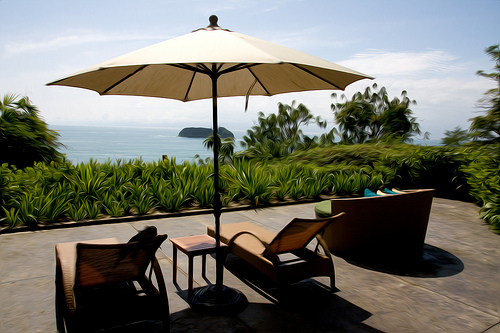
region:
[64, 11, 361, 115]
tan umbrella on porch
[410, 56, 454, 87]
white clouds in blue sky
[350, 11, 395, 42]
white clouds in blue sky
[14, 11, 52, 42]
white clouds in blue sky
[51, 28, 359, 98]
tan colored open umbrella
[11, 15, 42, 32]
white clouds in blue sky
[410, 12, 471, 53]
white clouds in blue sky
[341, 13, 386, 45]
white clouds in blue sky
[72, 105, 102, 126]
white clouds in blue sky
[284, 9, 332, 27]
white clouds in blue sky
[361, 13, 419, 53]
white clouds in blue sky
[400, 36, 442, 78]
white clouds in blue sky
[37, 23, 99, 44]
white clouds in blue sky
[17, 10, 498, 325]
a seating area on a patio.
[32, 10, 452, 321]
Lawn furniture on a large deck.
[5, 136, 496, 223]
Low green bushes surround the patio.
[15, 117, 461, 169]
A body of water.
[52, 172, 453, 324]
A seating area looking out over the water.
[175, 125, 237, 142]
A large rock in the water.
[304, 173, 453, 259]
A round wicker seat with pillows.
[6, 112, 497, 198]
A view of the ocean.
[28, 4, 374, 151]
this is an umbrella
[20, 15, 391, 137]
the umbrella is tan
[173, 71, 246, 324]
pole for the umbrella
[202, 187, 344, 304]
a patio recliner chair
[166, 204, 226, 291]
a square wooden table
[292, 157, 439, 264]
a round patio chair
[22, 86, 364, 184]
the ocean in the distance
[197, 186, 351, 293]
patio chair is brown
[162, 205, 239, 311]
table is brown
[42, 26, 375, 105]
The opened top of a tan umbrella.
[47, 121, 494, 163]
Blue ocean going across.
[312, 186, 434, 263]
A larger brown and green high back chair with blue and white pillows.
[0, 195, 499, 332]
A large tiled area around the patio.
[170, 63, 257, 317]
Black poles holding up the umbrella and keeping it open.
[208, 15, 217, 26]
Round black top on an umbrella.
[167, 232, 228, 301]
Small wood table between the chairs.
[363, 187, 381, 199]
Most visible blue pillow in a chair.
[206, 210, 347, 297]
More visible beige chair.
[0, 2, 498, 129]
Blue sky with white clouds.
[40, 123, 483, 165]
blue and clear ocean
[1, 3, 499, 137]
blue sky with clouds in it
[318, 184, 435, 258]
green and brown chair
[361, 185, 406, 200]
blue and yellow pillows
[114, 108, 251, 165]
A rock in the middle of the ocean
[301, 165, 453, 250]
A round chair on a porch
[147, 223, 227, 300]
A small brown table on a porch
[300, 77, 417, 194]
Several green bushes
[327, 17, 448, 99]
Blue sky with white clouds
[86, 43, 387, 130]
a view of umbrella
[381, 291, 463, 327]
a view of surface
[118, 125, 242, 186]
a view of trees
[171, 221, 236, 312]
a view of table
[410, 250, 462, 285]
a view of shadow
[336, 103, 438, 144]
a view of trees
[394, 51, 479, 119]
a view of clouds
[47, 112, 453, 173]
ocean in front of the patio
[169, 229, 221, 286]
table on the patio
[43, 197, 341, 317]
reclining chairs on the patio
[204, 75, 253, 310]
stand for the umbrella